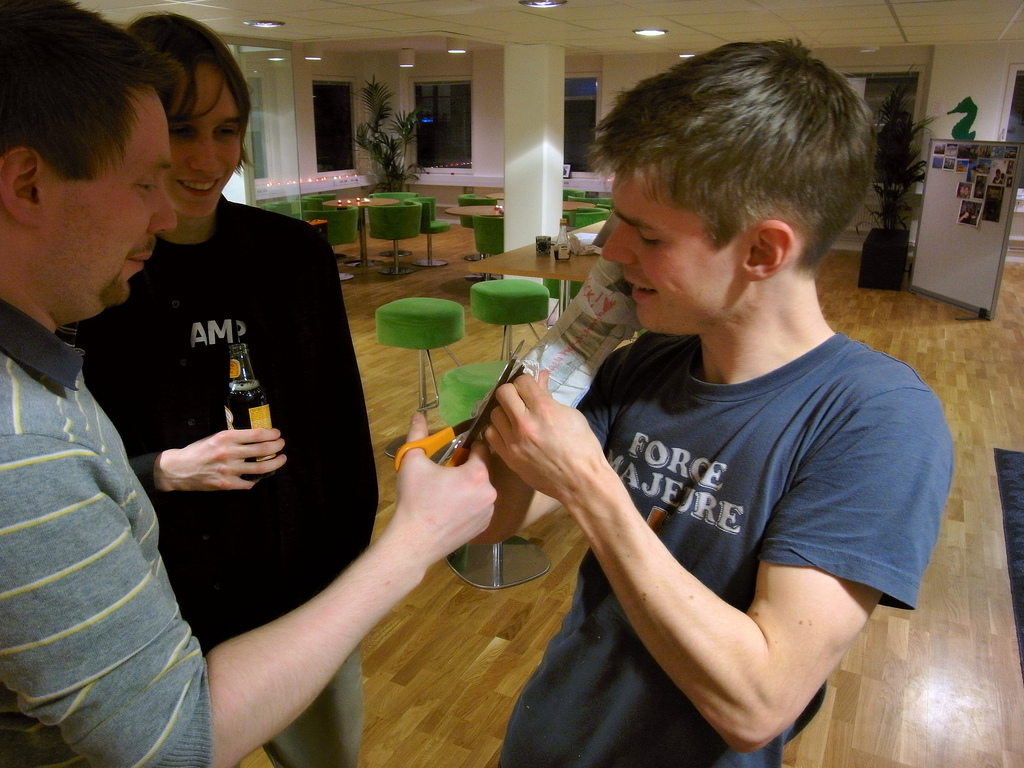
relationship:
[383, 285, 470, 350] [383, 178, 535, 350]
seat next to table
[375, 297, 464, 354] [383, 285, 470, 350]
cushion on seat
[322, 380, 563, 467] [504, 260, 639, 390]
scissors cutting cast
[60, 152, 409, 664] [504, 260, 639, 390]
person wearing cast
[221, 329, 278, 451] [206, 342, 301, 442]
hand holding bottle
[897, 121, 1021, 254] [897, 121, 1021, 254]
pictures on board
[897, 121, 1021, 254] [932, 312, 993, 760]
board on floor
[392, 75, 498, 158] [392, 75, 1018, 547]
window in room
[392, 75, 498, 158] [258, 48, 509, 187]
window on wall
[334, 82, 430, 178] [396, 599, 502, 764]
plant on wooden floor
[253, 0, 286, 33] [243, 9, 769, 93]
light in ceiling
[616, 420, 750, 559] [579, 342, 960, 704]
design in shirt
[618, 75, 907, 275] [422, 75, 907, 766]
haircut on man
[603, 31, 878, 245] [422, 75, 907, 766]
hair on man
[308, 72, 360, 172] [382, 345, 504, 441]
windows on wall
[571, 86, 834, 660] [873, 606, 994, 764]
boy on wooden floor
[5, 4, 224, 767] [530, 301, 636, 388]
man in cast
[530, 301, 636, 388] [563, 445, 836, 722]
cast on arm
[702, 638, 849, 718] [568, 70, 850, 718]
elbow on man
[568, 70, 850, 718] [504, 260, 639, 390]
man cutting cast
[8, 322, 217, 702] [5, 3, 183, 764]
shirt on man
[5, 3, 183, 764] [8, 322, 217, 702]
man wearing shirt